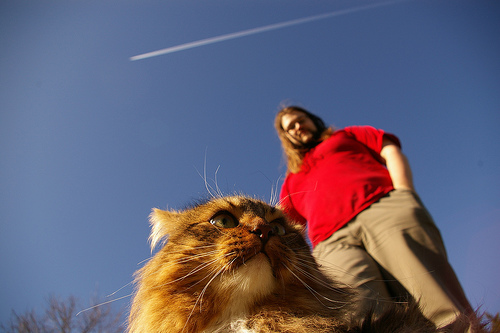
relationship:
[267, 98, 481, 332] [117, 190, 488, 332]
man near cat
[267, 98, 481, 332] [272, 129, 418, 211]
man in shirt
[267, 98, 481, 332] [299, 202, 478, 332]
man in pants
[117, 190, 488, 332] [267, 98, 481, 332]
cat in front of man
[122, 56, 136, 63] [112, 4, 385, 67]
plane making trail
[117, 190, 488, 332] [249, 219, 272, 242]
cat has nose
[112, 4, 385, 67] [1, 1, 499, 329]
trail in sky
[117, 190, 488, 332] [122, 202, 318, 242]
cat has ears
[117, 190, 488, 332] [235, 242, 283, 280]
cat has mouth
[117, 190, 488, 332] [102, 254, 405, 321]
cat has whiskers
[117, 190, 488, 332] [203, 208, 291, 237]
cat has eyes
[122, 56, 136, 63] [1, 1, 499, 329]
plane in sky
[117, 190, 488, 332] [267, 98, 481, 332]
cat near man